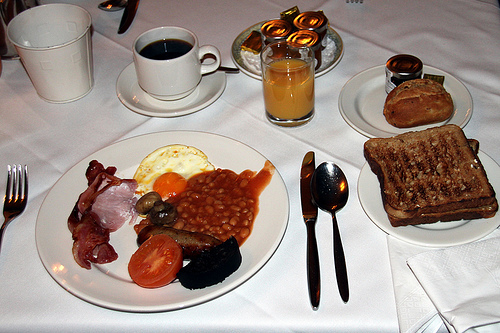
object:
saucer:
[113, 59, 227, 118]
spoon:
[309, 160, 351, 303]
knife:
[299, 150, 322, 310]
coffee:
[140, 39, 189, 60]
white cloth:
[368, 0, 500, 50]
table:
[0, 0, 500, 333]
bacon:
[67, 160, 134, 272]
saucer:
[355, 151, 500, 246]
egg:
[132, 144, 215, 198]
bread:
[403, 143, 456, 190]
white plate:
[33, 129, 293, 313]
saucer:
[338, 63, 475, 139]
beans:
[165, 169, 258, 243]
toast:
[359, 124, 497, 228]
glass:
[258, 49, 318, 127]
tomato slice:
[127, 234, 187, 288]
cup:
[132, 25, 220, 101]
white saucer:
[115, 56, 230, 118]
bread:
[363, 124, 497, 228]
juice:
[263, 59, 315, 120]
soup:
[64, 141, 277, 288]